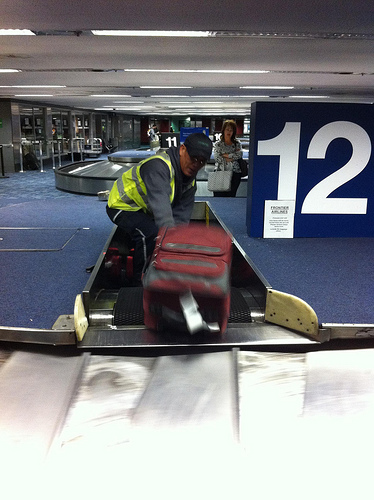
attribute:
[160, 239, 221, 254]
stripe — black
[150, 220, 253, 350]
suitcase — red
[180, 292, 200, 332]
tag — white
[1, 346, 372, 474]
belt — silver colored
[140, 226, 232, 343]
luggage — red, black, carousel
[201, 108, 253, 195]
woman — standing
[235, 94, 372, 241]
sign — blue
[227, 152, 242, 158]
arm — crossed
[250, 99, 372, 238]
sign — white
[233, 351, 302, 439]
belt — silver colored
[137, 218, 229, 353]
suitcase — Red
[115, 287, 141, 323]
belt — conveyer 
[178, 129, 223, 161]
cap — blue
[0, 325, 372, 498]
belt — silver colored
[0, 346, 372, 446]
belt — silver colored, Silver circular , airport 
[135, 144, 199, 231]
shirt — gray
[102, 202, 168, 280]
pants — blue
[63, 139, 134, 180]
belt peice — silver colored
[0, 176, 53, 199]
carpet — Blue patterened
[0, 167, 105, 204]
floor — airport 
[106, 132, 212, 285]
man — Dark navy blue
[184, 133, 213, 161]
cap — man's baseball 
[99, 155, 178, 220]
vest — Airport worker's bright yellow safety 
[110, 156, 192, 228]
vest — gray, yellow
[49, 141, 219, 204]
carosuel — empty